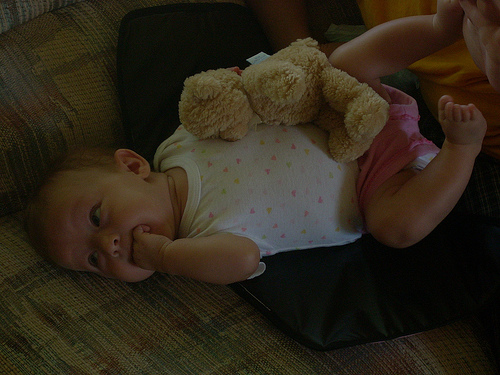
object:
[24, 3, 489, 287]
baby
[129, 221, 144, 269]
mouth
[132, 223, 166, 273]
hand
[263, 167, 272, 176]
heart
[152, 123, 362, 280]
onesie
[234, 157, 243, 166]
heart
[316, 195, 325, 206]
heart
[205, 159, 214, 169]
heart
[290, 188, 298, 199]
heart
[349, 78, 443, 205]
shorts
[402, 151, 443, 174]
diaper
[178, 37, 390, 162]
teddy bear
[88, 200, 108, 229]
eye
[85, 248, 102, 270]
eye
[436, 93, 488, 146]
foot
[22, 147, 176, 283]
head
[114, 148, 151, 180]
ear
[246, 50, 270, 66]
tag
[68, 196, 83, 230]
eyebrow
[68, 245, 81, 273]
eyebrow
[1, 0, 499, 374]
couch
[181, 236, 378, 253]
back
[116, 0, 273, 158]
object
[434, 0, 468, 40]
foot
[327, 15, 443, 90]
leg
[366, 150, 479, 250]
leg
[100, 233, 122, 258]
nose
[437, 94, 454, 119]
toes